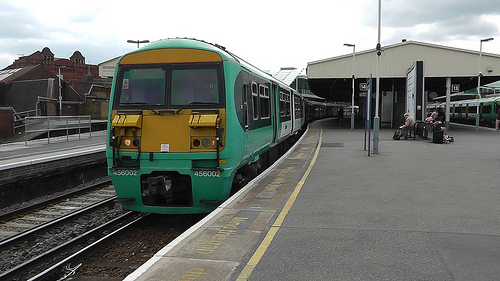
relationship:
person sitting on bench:
[391, 111, 417, 142] [406, 118, 438, 144]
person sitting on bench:
[426, 108, 453, 143] [406, 118, 438, 144]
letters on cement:
[167, 133, 316, 280] [134, 122, 500, 280]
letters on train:
[109, 164, 224, 181] [102, 29, 358, 226]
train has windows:
[102, 29, 358, 226] [116, 61, 226, 108]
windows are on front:
[116, 61, 226, 108] [100, 30, 245, 220]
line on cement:
[230, 122, 322, 279] [134, 122, 500, 280]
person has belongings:
[391, 111, 417, 142] [390, 128, 406, 143]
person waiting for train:
[391, 111, 417, 142] [102, 29, 358, 226]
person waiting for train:
[426, 108, 453, 143] [102, 29, 358, 226]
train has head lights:
[102, 29, 358, 226] [111, 132, 222, 154]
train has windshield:
[102, 29, 358, 226] [115, 64, 227, 111]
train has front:
[102, 29, 358, 226] [100, 30, 245, 220]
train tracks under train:
[3, 205, 153, 277] [102, 29, 358, 226]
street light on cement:
[337, 39, 361, 140] [134, 122, 500, 280]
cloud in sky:
[356, 2, 498, 44] [2, 0, 499, 72]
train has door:
[102, 29, 358, 226] [266, 80, 284, 147]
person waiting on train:
[391, 111, 417, 142] [102, 29, 358, 226]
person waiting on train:
[426, 108, 453, 143] [102, 29, 358, 226]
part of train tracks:
[34, 222, 106, 269] [3, 205, 153, 277]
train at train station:
[102, 29, 358, 226] [0, 31, 499, 279]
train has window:
[102, 29, 358, 226] [248, 78, 262, 125]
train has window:
[102, 29, 358, 226] [257, 80, 274, 126]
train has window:
[102, 29, 358, 226] [276, 90, 288, 121]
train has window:
[102, 29, 358, 226] [285, 91, 295, 121]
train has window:
[102, 29, 358, 226] [294, 93, 304, 121]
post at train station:
[395, 57, 430, 120] [0, 31, 499, 279]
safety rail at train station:
[20, 108, 97, 152] [0, 31, 499, 279]